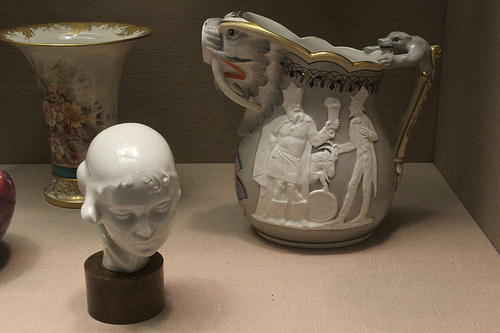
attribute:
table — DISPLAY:
[270, 289, 371, 309]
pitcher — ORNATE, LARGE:
[212, 17, 458, 245]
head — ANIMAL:
[195, 21, 269, 110]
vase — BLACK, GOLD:
[196, 20, 436, 247]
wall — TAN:
[456, 50, 484, 102]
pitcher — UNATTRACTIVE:
[197, 25, 470, 259]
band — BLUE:
[51, 167, 71, 181]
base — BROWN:
[102, 281, 151, 316]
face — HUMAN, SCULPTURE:
[101, 180, 186, 257]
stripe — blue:
[28, 161, 99, 191]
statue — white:
[67, 109, 197, 284]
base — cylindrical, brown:
[75, 257, 177, 327]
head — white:
[61, 110, 181, 275]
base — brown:
[70, 250, 194, 329]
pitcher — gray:
[199, 9, 452, 280]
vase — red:
[3, 229, 11, 248]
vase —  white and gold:
[2, 57, 152, 136]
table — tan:
[0, 158, 485, 331]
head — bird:
[204, 15, 284, 117]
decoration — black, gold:
[280, 63, 379, 103]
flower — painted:
[40, 79, 75, 132]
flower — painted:
[43, 73, 61, 98]